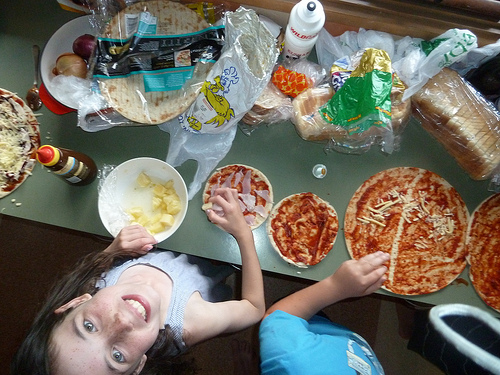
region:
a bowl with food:
[96, 156, 186, 250]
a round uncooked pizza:
[198, 162, 281, 235]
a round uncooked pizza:
[265, 187, 340, 274]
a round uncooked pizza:
[340, 159, 470, 298]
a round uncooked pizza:
[462, 186, 499, 316]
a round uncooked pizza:
[0, 82, 42, 204]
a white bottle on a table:
[280, 0, 328, 72]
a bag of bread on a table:
[409, 62, 499, 180]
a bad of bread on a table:
[287, 65, 414, 145]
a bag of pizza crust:
[90, 2, 218, 123]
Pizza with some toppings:
[203, 164, 270, 234]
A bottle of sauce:
[34, 143, 96, 184]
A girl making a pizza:
[14, 188, 266, 374]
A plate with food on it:
[97, 156, 187, 245]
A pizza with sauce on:
[265, 190, 339, 267]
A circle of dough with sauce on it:
[343, 167, 473, 294]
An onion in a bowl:
[52, 53, 84, 82]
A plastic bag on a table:
[325, 49, 396, 154]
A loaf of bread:
[406, 68, 498, 179]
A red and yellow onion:
[52, 54, 87, 81]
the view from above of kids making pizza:
[3, 8, 473, 351]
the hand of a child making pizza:
[268, 248, 414, 369]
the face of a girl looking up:
[28, 255, 168, 372]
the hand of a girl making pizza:
[197, 183, 256, 243]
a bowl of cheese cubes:
[97, 153, 192, 252]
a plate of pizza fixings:
[341, 151, 469, 303]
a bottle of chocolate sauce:
[31, 136, 100, 194]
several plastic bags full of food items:
[33, 2, 485, 177]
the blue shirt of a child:
[256, 303, 388, 373]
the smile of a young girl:
[117, 293, 157, 325]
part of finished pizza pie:
[0, 84, 37, 206]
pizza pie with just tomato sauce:
[262, 186, 341, 266]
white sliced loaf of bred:
[420, 72, 498, 175]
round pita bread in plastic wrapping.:
[90, 4, 217, 121]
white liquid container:
[287, 1, 324, 68]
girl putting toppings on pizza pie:
[35, 163, 263, 373]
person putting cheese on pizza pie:
[257, 159, 464, 373]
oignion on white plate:
[50, 50, 85, 80]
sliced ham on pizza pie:
[237, 172, 272, 206]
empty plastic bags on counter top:
[327, 32, 472, 69]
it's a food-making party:
[2, 0, 497, 367]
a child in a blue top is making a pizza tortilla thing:
[251, 160, 462, 372]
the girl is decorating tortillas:
[10, 150, 340, 370]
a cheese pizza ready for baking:
[0, 80, 40, 205]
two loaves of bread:
[285, 45, 495, 185]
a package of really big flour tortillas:
[91, 0, 215, 129]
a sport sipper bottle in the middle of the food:
[276, 0, 332, 72]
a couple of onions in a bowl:
[36, 10, 132, 116]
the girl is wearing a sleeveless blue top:
[15, 243, 237, 373]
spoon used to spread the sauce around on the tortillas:
[21, 38, 45, 118]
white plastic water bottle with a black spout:
[279, 0, 323, 64]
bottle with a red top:
[34, 145, 96, 188]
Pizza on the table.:
[264, 180, 492, 277]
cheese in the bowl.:
[122, 180, 178, 225]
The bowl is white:
[97, 165, 189, 238]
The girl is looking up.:
[49, 287, 176, 365]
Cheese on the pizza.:
[378, 195, 458, 239]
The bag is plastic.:
[96, 9, 217, 91]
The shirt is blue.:
[256, 318, 363, 374]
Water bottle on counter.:
[284, 10, 322, 61]